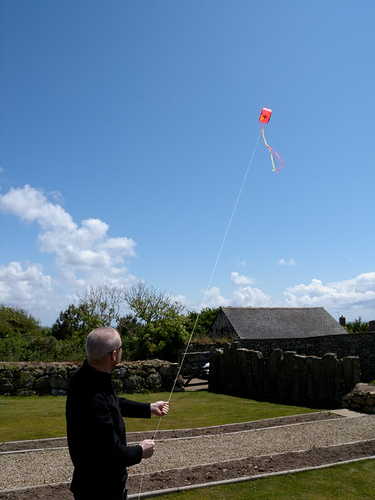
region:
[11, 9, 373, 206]
The sky is clear blue.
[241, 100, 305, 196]
The kite is red.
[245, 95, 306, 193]
The kite has a tail.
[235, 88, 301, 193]
The kite is flying.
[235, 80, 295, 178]
The kite is in the air.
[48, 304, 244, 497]
The man is flying a kite.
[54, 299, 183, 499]
He has a black shirt.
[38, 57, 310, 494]
He is holding the string.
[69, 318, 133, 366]
He has glasses on.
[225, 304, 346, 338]
The roof is gray.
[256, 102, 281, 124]
THE KITE IS IN THE AIR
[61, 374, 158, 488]
the clothes are black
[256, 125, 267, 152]
string is attached to the kite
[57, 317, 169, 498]
the man has glasses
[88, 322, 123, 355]
the hair is white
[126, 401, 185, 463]
hands are holding th string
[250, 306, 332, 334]
the roof is grey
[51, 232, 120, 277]
clouds are in the sky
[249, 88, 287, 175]
the kite in the air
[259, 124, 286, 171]
the strings on the kite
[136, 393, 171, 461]
the hands hold the kite string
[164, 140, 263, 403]
the kite string stretched out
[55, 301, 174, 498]
the man flying the kite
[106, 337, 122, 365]
the sunglasses on the mans face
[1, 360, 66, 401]
the stone wall behind the grass lawn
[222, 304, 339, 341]
the roof of the building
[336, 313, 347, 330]
the chimney poking out over the roof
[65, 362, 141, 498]
the black long sleeve shirt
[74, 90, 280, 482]
the man is flying a kite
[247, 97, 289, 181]
it is a box style kite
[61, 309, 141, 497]
the man is wearing black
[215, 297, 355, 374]
a building is to the right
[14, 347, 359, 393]
the area is surrounded by a rock wall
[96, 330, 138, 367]
the man is wearing glasses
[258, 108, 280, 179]
the tail of the kite is green & pink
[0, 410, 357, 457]
the path way is gravel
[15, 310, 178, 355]
a thicket of trees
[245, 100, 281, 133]
the kite appears to have a cross on it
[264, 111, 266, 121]
A kite in the air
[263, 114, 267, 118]
A cross on the kite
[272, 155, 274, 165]
Tail on the kite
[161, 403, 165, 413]
Hand holding the string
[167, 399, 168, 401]
String on the hand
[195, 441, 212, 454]
Bright gravel on the ground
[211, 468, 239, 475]
Dark surface on the ground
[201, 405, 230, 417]
Surface covered with grass